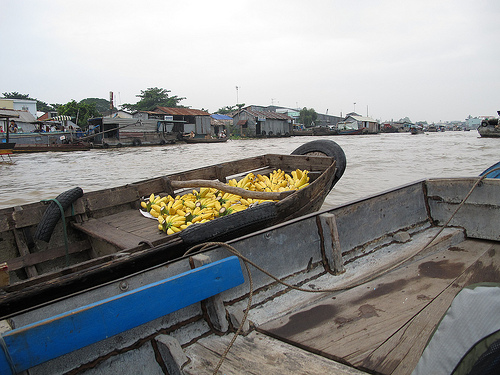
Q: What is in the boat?
A: Fruits.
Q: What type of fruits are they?
A: Bananas.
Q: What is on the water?
A: Boats.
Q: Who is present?
A: Nobody.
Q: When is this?
A: Daytime.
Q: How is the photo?
A: Clear.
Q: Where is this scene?
A: On the water.